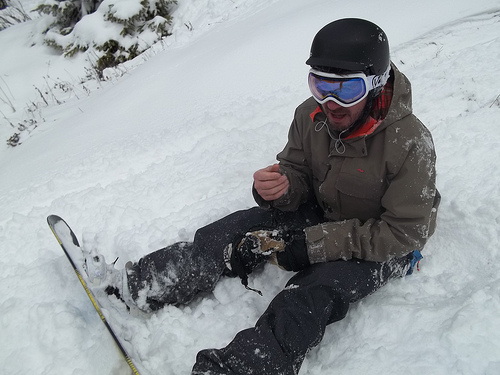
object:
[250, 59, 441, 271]
hoody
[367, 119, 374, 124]
red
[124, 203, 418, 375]
pants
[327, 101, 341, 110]
nose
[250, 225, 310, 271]
hand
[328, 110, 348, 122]
mouth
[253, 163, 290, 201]
fingers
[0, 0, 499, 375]
ground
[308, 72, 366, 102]
goggle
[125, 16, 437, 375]
man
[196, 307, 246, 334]
snow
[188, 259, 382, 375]
leg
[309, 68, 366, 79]
lining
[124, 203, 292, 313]
legs